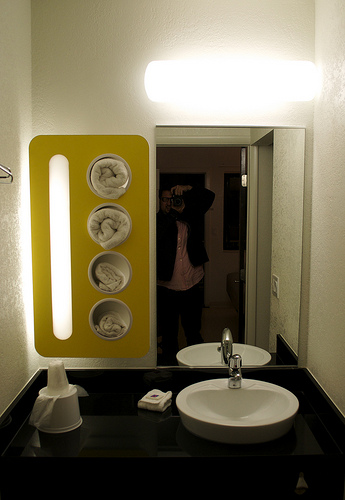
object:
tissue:
[27, 395, 60, 429]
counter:
[0, 396, 324, 473]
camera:
[172, 189, 183, 208]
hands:
[171, 185, 183, 196]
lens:
[165, 198, 168, 201]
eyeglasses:
[161, 197, 170, 202]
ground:
[160, 299, 227, 367]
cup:
[47, 358, 69, 394]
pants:
[156, 276, 205, 366]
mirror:
[156, 128, 306, 368]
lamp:
[47, 152, 72, 341]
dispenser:
[35, 383, 82, 432]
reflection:
[155, 184, 215, 365]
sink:
[176, 374, 301, 443]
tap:
[229, 353, 242, 369]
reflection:
[221, 328, 234, 364]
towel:
[137, 388, 172, 413]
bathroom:
[0, 0, 345, 500]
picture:
[2, 2, 343, 498]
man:
[156, 183, 216, 366]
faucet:
[228, 354, 242, 390]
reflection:
[102, 422, 177, 458]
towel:
[90, 158, 129, 199]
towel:
[88, 208, 131, 249]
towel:
[95, 263, 125, 293]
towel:
[95, 314, 127, 338]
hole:
[87, 153, 132, 201]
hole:
[87, 202, 132, 244]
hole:
[87, 250, 131, 296]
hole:
[88, 296, 132, 340]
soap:
[148, 392, 163, 399]